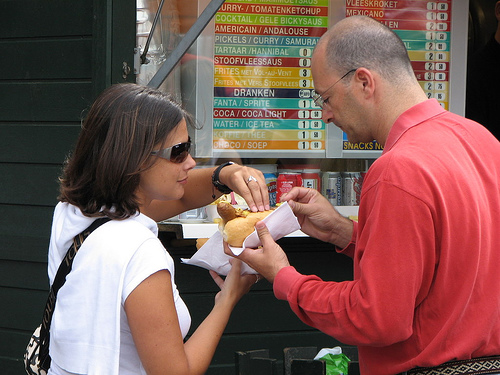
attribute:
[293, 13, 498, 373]
man — balding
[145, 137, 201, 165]
sunglasses — black, gray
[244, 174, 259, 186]
ring — silver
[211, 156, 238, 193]
watch — black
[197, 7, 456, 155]
sign — menu, with Menu, with  prices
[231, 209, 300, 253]
napkin — white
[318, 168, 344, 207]
can — silver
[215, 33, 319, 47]
text — white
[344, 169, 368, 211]
soda can — gray, red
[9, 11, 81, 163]
wall — wooden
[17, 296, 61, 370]
purse — black, white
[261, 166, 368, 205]
cans —  soda's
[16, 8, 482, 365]
stand — deep black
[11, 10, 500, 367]
season — summer